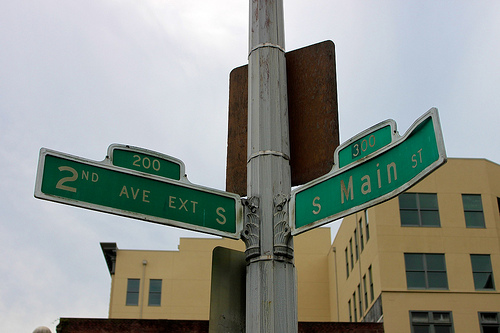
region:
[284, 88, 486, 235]
the sign is green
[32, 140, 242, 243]
sign for 2nd avenue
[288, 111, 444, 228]
sign for south main street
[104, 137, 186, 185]
sign indicating the 200th block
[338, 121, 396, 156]
sign indicating the 300th block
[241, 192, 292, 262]
brackets on a street pole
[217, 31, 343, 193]
the back of a street sign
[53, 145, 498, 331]
a tan colored building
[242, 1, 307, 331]
a skinny sign pole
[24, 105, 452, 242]
two green street signs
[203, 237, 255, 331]
the back of a street sign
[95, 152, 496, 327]
The large yellow building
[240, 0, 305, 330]
The grey pole with the signs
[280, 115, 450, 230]
The green sign with main st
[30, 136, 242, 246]
The sign with 2nd ave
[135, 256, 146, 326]
The pole between the windows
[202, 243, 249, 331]
The back of the silver sign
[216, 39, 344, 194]
The back of the brown sign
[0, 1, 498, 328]
The sky above the building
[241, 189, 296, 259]
The braces holding the street signs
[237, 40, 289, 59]
The top ring of the brown sign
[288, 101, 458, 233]
The sign with main st on it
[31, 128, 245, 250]
The sign with 2nd ave on it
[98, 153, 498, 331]
The yellow building in the background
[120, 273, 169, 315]
The two windows by themselves of the building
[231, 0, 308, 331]
The pole the signs are on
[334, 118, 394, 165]
The small sign with 300 on it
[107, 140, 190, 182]
The small sign with 200 on it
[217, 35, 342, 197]
The brown black of the sign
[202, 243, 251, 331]
The silver back of a sign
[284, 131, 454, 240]
Green street sign says "S Main ST"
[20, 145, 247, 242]
Green street sign says "2nd Ave Ext S"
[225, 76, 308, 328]
Street sign pole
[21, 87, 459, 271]
Two street signs on gray pole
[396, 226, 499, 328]
Window in building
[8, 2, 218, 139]
Clear blue sky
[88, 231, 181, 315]
Two windows in distant building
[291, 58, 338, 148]
Back of a sign hanging on pole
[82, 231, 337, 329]
Tan building in distance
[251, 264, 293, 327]
Pattern of gray street sign pole